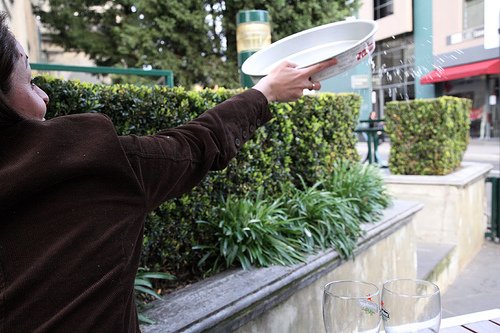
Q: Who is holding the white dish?
A: A woman.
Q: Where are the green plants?
A: In front of the bushes.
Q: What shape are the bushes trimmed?
A: Square.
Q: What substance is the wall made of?
A: Concrete.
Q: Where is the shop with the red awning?
A: Across the street.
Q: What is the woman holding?
A: A white dish.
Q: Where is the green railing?
A: Behind the bushes.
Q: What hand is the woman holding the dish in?
A: Right.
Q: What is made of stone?
A: The wall.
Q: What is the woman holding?
A: A pan.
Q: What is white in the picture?
A: The dish the woman is holding.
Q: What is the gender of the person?
A: Female.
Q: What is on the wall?
A: Plants.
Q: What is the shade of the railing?
A: Green.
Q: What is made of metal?
A: The railing.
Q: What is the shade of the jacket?
A: Brown.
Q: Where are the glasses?
A: On table.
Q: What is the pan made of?
A: Metal.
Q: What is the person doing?
A: Holding a bowl.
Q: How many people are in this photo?
A: One.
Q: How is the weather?
A: Clear.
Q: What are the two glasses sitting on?
A: A table.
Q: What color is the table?
A: White.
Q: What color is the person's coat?
A: Brown.